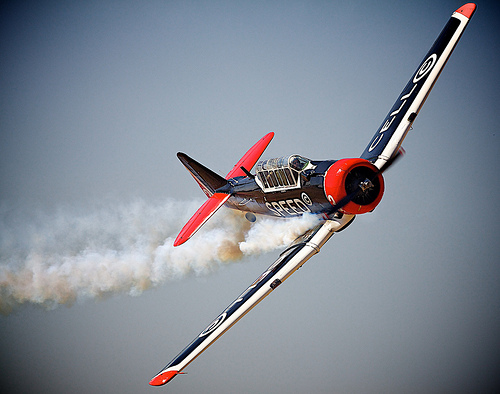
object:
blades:
[322, 186, 362, 220]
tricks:
[0, 0, 479, 392]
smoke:
[0, 194, 321, 313]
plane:
[145, 1, 480, 389]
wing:
[145, 217, 338, 387]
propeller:
[321, 144, 408, 220]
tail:
[172, 130, 279, 247]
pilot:
[289, 157, 305, 180]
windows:
[255, 153, 312, 189]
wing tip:
[147, 370, 178, 387]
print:
[366, 51, 438, 154]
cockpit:
[251, 152, 319, 193]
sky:
[0, 0, 500, 394]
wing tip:
[451, 1, 479, 19]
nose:
[322, 156, 385, 216]